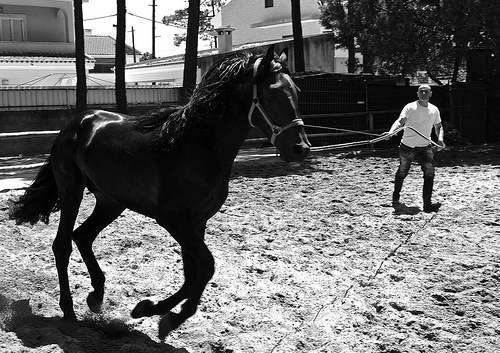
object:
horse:
[5, 40, 312, 342]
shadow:
[264, 217, 433, 353]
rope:
[311, 125, 409, 155]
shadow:
[1, 296, 195, 351]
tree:
[314, 0, 369, 73]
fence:
[367, 83, 450, 146]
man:
[384, 81, 449, 213]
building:
[0, 1, 79, 64]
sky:
[81, 2, 188, 56]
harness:
[244, 54, 318, 165]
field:
[0, 142, 500, 350]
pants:
[389, 142, 444, 213]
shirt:
[394, 99, 446, 152]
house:
[207, 0, 361, 70]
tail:
[6, 128, 67, 228]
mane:
[134, 46, 255, 138]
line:
[144, 0, 162, 59]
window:
[10, 14, 28, 44]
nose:
[278, 138, 317, 166]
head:
[237, 44, 314, 163]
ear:
[252, 37, 283, 85]